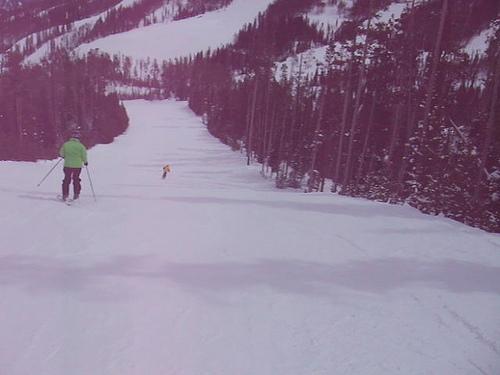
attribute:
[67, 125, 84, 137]
hat — green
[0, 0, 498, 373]
snow — white, fluffy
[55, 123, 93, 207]
skier — male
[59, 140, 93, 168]
jacket — green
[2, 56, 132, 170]
green trees — prickly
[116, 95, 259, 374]
snow path — smooth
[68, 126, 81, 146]
head — back 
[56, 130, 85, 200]
person — skiing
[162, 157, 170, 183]
person — skiing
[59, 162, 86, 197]
pants — black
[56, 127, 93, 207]
jacket — green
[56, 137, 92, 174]
jacket — green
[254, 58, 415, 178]
trees — tall, prickly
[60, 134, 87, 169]
jacket — green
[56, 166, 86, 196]
pants — black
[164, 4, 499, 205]
slope — snowy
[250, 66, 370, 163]
trees — bare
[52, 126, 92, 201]
person — skiing